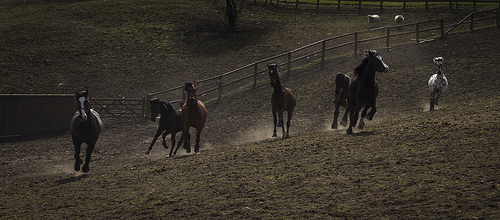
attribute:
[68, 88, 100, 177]
horse — brown, running, black, white, dark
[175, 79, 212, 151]
horse — brown, running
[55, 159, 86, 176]
dust — kicked up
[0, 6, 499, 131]
fence — wooden, long, broken, brown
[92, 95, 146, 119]
door — large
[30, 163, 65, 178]
dirt — dry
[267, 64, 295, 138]
horse — running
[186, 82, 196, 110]
head — white, brown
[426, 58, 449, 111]
horse — white, running